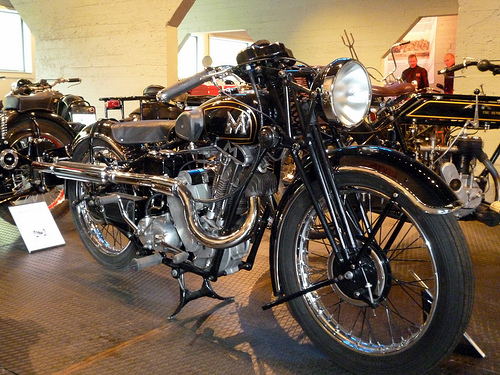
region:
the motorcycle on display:
[56, 36, 446, 373]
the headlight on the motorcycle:
[288, 47, 396, 137]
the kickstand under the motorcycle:
[152, 271, 251, 328]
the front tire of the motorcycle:
[271, 148, 480, 362]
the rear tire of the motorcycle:
[63, 119, 155, 273]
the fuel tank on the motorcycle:
[187, 92, 272, 141]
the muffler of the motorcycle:
[19, 155, 176, 201]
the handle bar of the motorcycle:
[86, 55, 355, 111]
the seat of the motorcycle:
[93, 98, 185, 153]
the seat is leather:
[106, 115, 165, 148]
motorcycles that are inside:
[12, 44, 497, 336]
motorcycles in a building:
[17, 35, 497, 305]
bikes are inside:
[6, 39, 498, 331]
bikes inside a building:
[9, 37, 491, 364]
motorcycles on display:
[72, 69, 488, 351]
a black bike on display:
[77, 39, 462, 336]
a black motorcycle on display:
[67, 53, 447, 347]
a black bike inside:
[70, 63, 461, 360]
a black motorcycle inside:
[71, 26, 469, 373]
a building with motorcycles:
[73, 25, 498, 336]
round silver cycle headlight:
[314, 46, 385, 135]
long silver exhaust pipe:
[27, 147, 267, 259]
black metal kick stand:
[151, 248, 243, 345]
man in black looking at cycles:
[396, 46, 435, 91]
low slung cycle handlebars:
[152, 43, 385, 118]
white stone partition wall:
[16, 3, 204, 85]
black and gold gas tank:
[184, 85, 276, 150]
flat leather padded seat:
[110, 109, 187, 154]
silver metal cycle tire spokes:
[295, 178, 447, 365]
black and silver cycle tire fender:
[252, 134, 472, 306]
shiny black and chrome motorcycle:
[64, 59, 472, 370]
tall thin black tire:
[271, 151, 468, 367]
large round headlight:
[314, 60, 380, 135]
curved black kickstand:
[167, 262, 235, 319]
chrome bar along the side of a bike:
[41, 147, 268, 251]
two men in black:
[391, 34, 464, 108]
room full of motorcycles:
[5, 36, 498, 331]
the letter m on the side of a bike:
[201, 94, 256, 144]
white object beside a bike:
[6, 205, 65, 257]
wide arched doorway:
[165, 14, 267, 121]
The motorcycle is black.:
[68, 52, 483, 372]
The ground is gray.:
[25, 272, 112, 334]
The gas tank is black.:
[179, 78, 281, 153]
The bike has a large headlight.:
[318, 47, 379, 140]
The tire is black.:
[268, 149, 485, 373]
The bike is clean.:
[58, 47, 478, 374]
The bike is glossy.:
[62, 40, 484, 374]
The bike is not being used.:
[61, 41, 483, 366]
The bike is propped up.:
[138, 225, 258, 337]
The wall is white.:
[84, 10, 154, 70]